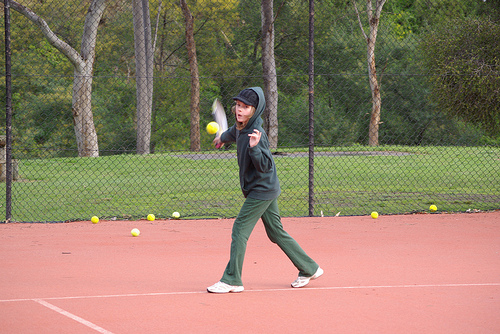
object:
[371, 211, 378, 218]
ball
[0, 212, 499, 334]
ground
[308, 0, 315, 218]
pole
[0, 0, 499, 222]
fence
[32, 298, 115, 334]
line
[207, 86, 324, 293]
girl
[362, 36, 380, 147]
tree trunk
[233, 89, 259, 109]
hat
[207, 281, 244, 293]
shoe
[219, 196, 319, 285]
trouser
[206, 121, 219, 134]
ball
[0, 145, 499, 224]
field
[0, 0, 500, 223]
background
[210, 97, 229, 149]
racket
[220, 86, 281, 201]
hoodie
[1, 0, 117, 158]
tree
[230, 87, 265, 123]
head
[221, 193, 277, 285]
leg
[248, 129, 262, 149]
hand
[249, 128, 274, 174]
arm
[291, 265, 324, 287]
shoe